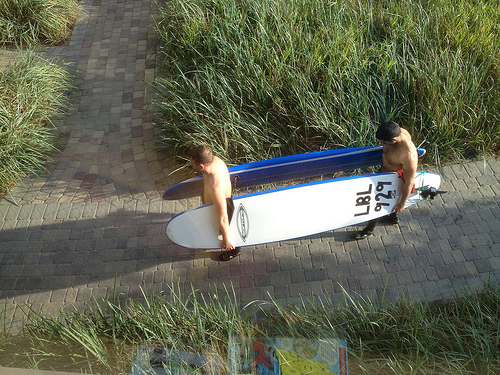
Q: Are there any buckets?
A: No, there are no buckets.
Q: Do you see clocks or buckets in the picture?
A: No, there are no buckets or clocks.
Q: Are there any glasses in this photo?
A: No, there are no glasses.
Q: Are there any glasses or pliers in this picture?
A: No, there are no glasses or pliers.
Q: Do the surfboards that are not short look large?
A: Yes, the surfboards are large.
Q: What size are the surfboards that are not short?
A: The surfboards are large.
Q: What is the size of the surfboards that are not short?
A: The surfboards are large.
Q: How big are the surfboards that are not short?
A: The surfboards are large.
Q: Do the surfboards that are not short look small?
A: No, the surfboards are large.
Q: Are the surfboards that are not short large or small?
A: The surfboards are large.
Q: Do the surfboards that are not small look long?
A: Yes, the surfboards are long.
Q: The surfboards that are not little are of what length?
A: The surfboards are long.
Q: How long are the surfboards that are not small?
A: The surfboards are long.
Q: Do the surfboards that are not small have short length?
A: No, the surfboards are long.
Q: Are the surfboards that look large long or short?
A: The surfboards are long.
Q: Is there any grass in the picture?
A: Yes, there is grass.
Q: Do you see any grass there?
A: Yes, there is grass.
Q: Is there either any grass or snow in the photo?
A: Yes, there is grass.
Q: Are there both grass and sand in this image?
A: No, there is grass but no sand.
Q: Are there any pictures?
A: No, there are no pictures.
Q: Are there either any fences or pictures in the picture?
A: No, there are no pictures or fences.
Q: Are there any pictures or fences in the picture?
A: No, there are no pictures or fences.